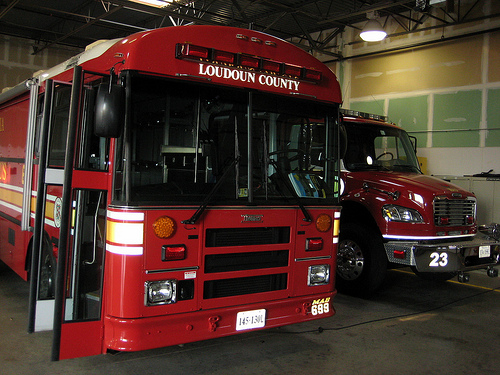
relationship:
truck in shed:
[1, 22, 344, 359] [2, 2, 499, 374]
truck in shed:
[337, 105, 499, 293] [2, 2, 499, 374]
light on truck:
[152, 216, 178, 240] [1, 22, 344, 359]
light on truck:
[314, 212, 333, 233] [1, 22, 344, 359]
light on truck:
[160, 243, 188, 264] [1, 22, 344, 359]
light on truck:
[303, 235, 325, 251] [1, 22, 344, 359]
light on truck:
[144, 276, 179, 306] [1, 22, 344, 359]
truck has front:
[1, 22, 344, 359] [102, 20, 339, 352]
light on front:
[152, 216, 178, 240] [102, 20, 339, 352]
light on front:
[314, 212, 333, 233] [102, 20, 339, 352]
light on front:
[160, 243, 188, 264] [102, 20, 339, 352]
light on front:
[303, 235, 325, 251] [102, 20, 339, 352]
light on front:
[144, 276, 179, 306] [102, 20, 339, 352]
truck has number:
[337, 105, 499, 293] [427, 249, 451, 269]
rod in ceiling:
[305, 0, 424, 27] [2, 1, 499, 50]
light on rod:
[356, 12, 388, 43] [305, 0, 424, 27]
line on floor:
[393, 266, 499, 295] [3, 252, 500, 374]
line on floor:
[376, 311, 437, 331] [3, 252, 500, 374]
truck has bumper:
[337, 105, 499, 293] [385, 229, 499, 275]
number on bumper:
[427, 249, 451, 269] [385, 229, 499, 275]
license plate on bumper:
[477, 243, 495, 260] [385, 229, 499, 275]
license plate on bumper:
[235, 306, 269, 332] [106, 290, 337, 358]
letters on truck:
[196, 60, 302, 94] [1, 22, 344, 359]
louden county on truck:
[195, 59, 302, 91] [1, 22, 344, 359]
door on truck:
[50, 63, 115, 362] [1, 22, 344, 359]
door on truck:
[25, 76, 88, 336] [1, 22, 344, 359]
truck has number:
[1, 22, 344, 359] [310, 300, 334, 317]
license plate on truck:
[477, 243, 495, 260] [337, 105, 499, 293]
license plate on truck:
[235, 306, 269, 332] [1, 22, 344, 359]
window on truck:
[32, 82, 75, 159] [1, 22, 344, 359]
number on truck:
[427, 249, 451, 269] [337, 105, 499, 293]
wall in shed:
[282, 1, 498, 264] [2, 2, 499, 374]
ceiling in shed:
[2, 1, 499, 50] [2, 2, 499, 374]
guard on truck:
[17, 76, 39, 232] [1, 22, 344, 359]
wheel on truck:
[336, 217, 390, 303] [337, 105, 499, 293]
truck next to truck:
[1, 22, 344, 359] [337, 105, 499, 293]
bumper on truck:
[385, 229, 499, 275] [337, 105, 499, 293]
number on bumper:
[310, 300, 334, 317] [106, 290, 337, 358]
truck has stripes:
[1, 22, 344, 359] [0, 181, 146, 257]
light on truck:
[340, 106, 390, 124] [337, 105, 499, 293]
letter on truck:
[197, 59, 207, 76] [1, 22, 344, 359]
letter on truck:
[205, 63, 216, 77] [1, 22, 344, 359]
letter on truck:
[214, 64, 224, 77] [1, 22, 344, 359]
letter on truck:
[223, 66, 233, 79] [1, 22, 344, 359]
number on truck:
[310, 300, 334, 317] [1, 22, 344, 359]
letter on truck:
[287, 78, 297, 91] [1, 22, 344, 359]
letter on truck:
[293, 78, 304, 92] [1, 22, 344, 359]